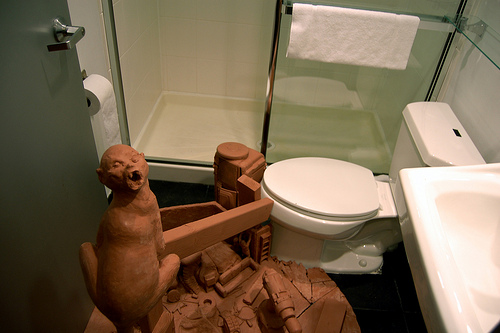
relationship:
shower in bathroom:
[107, 11, 463, 196] [5, 5, 492, 326]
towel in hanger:
[287, 4, 419, 87] [276, 0, 466, 43]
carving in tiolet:
[74, 140, 361, 332] [256, 76, 488, 310]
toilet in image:
[257, 99, 484, 275] [6, 3, 497, 331]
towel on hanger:
[287, 4, 420, 73] [276, 0, 466, 35]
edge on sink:
[387, 139, 481, 330] [378, 126, 498, 326]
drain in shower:
[255, 126, 275, 155] [104, 0, 467, 184]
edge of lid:
[291, 190, 354, 239] [262, 145, 387, 226]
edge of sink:
[387, 163, 442, 333] [385, 108, 498, 330]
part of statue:
[163, 192, 276, 287] [69, 116, 384, 331]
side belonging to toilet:
[270, 226, 384, 275] [257, 99, 485, 272]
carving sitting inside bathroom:
[74, 140, 359, 331] [5, 5, 492, 326]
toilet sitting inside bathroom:
[257, 99, 485, 272] [5, 5, 492, 326]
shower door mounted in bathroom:
[259, 1, 465, 174] [5, 5, 492, 326]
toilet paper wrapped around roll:
[80, 72, 122, 149] [85, 95, 91, 107]